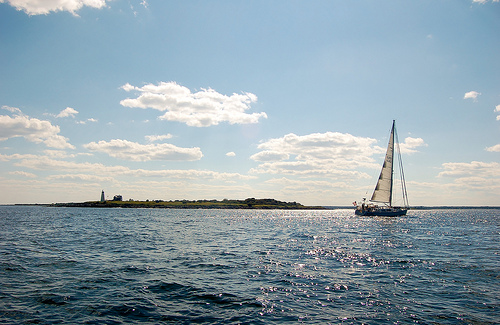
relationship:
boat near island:
[351, 119, 411, 216] [32, 181, 329, 215]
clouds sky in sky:
[45, 38, 265, 130] [2, 0, 498, 208]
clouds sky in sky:
[241, 130, 351, 185] [2, 0, 498, 208]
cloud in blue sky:
[120, 78, 266, 128] [112, 23, 293, 133]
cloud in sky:
[49, 107, 80, 119] [23, 72, 133, 139]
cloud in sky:
[120, 78, 266, 128] [2, 0, 498, 208]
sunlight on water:
[318, 244, 342, 256] [7, 210, 161, 319]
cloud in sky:
[83, 132, 207, 163] [12, 4, 489, 195]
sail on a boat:
[369, 120, 394, 204] [353, 199, 408, 221]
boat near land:
[351, 119, 411, 216] [33, 198, 303, 212]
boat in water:
[351, 119, 411, 216] [12, 201, 484, 311]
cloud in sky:
[250, 132, 428, 174] [2, 0, 498, 208]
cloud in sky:
[86, 135, 205, 168] [2, 0, 498, 208]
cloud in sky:
[1, 108, 73, 157] [2, 0, 498, 208]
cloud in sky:
[1, 0, 116, 22] [2, 0, 498, 208]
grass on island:
[168, 198, 219, 205] [77, 195, 307, 208]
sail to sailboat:
[369, 120, 395, 204] [350, 117, 410, 217]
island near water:
[18, 190, 346, 210] [2, 203, 498, 322]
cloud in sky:
[54, 106, 81, 121] [2, 0, 498, 208]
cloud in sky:
[250, 132, 379, 168] [2, 0, 498, 208]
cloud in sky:
[49, 107, 80, 119] [2, 0, 498, 208]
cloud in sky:
[83, 132, 207, 163] [2, 0, 498, 208]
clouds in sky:
[458, 85, 481, 102] [2, 0, 498, 208]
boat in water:
[351, 119, 411, 216] [2, 203, 498, 322]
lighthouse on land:
[98, 188, 105, 203] [8, 196, 307, 210]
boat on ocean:
[351, 119, 411, 216] [0, 203, 498, 318]